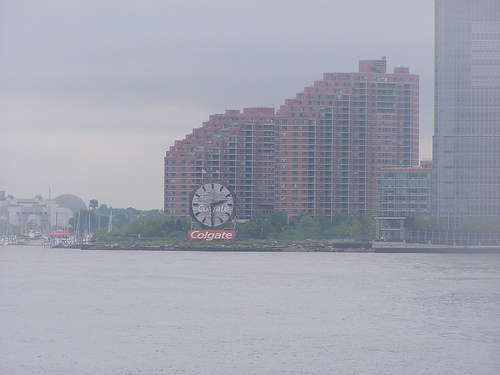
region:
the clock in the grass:
[183, 173, 247, 248]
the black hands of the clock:
[204, 193, 230, 233]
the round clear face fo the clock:
[190, 179, 235, 230]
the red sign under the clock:
[188, 227, 237, 244]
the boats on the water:
[0, 213, 95, 248]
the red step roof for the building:
[163, 49, 421, 170]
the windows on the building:
[280, 113, 368, 218]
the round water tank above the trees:
[85, 198, 100, 212]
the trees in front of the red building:
[239, 210, 373, 246]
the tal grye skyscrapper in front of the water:
[435, 2, 498, 235]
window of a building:
[165, 160, 177, 172]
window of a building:
[166, 170, 180, 178]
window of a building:
[205, 148, 219, 156]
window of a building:
[243, 122, 255, 129]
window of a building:
[238, 128, 256, 143]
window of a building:
[235, 153, 249, 168]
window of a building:
[237, 182, 257, 194]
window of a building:
[243, 196, 256, 207]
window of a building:
[237, 201, 252, 216]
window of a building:
[336, 160, 351, 174]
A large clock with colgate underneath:
[189, 180, 236, 242]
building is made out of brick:
[162, 55, 419, 230]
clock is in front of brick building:
[161, 56, 421, 242]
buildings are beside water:
[2, 0, 497, 372]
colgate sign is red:
[189, 227, 236, 242]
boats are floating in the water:
[2, 205, 497, 373]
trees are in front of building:
[69, 1, 496, 252]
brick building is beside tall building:
[162, 0, 498, 229]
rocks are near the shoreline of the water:
[0, 239, 497, 373]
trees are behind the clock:
[89, 183, 380, 240]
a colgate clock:
[185, 177, 246, 241]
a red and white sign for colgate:
[183, 223, 249, 244]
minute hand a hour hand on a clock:
[203, 193, 226, 227]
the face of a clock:
[193, 183, 233, 226]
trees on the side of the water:
[102, 203, 473, 285]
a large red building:
[145, 43, 430, 240]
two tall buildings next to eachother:
[140, 1, 499, 275]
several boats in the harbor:
[4, 199, 126, 252]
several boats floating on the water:
[3, 181, 127, 296]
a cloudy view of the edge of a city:
[7, 4, 499, 366]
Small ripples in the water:
[36, 332, 70, 354]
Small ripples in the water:
[69, 340, 100, 364]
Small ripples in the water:
[84, 317, 114, 344]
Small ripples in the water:
[113, 337, 153, 368]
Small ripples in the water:
[118, 294, 172, 334]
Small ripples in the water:
[159, 332, 179, 357]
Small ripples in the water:
[192, 332, 230, 357]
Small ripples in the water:
[240, 332, 270, 359]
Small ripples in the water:
[279, 339, 306, 354]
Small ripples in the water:
[315, 327, 348, 362]